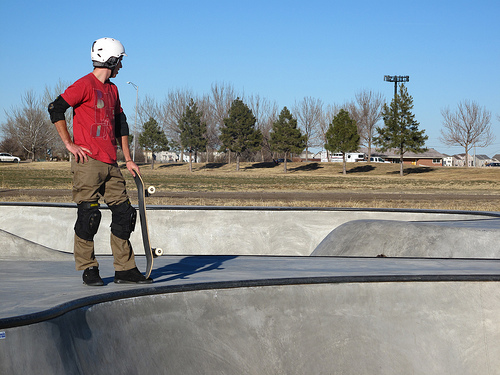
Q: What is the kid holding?
A: A skateboard.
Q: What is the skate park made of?
A: Cement.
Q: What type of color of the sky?
A: Blue.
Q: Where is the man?
A: Ramp.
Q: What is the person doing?
A: Holding a skateboard.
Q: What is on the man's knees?
A: Kneepads.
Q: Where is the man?
A: At a skatepark.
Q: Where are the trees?
A: Behind the skate park.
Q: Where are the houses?
A: Behind the trees.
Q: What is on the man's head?
A: Helmet.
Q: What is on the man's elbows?
A: Elbow pads.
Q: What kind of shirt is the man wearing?
A: Red t shirt.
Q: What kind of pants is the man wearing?
A: Khaki.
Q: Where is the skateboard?
A: Balanced between the man's hand and shoe.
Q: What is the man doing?
A: Skateboarding.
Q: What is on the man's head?
A: Helmet.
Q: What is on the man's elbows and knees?
A: Pads.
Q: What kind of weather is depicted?
A: Clear and sunny.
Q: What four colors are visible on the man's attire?
A: Red, black, brown and white.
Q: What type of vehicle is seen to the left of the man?
A: Automobile.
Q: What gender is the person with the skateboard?
A: Male.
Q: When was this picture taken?
A: Daytime.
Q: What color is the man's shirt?
A: Red.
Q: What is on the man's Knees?
A: Knee Pads.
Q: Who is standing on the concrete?
A: Skater.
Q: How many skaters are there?
A: 1.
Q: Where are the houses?
A: Behind the skatepark.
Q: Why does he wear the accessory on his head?
A: Safety.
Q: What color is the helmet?
A: White.